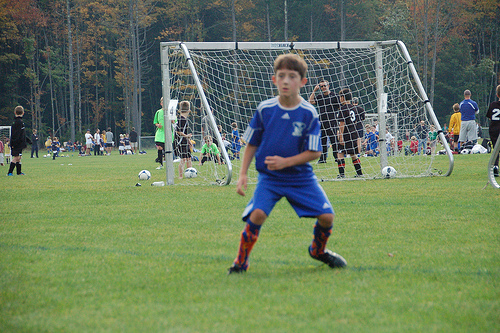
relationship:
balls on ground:
[132, 163, 411, 192] [119, 172, 213, 227]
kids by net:
[145, 90, 209, 156] [170, 55, 236, 127]